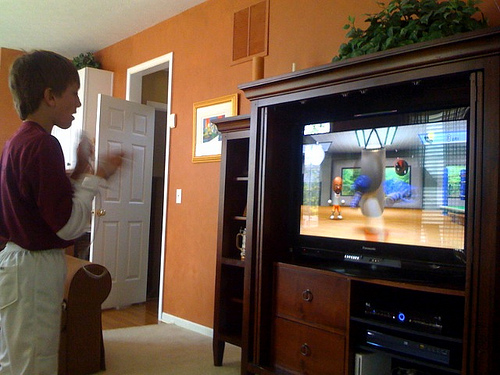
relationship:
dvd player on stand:
[356, 295, 459, 336] [240, 26, 498, 374]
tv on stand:
[282, 102, 469, 284] [240, 26, 498, 374]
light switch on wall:
[176, 188, 182, 203] [0, 1, 498, 325]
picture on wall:
[191, 92, 239, 163] [0, 1, 498, 325]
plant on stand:
[326, 1, 492, 64] [240, 26, 498, 374]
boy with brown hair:
[1, 50, 125, 374] [6, 48, 80, 121]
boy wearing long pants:
[1, 50, 125, 374] [0, 241, 65, 372]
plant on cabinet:
[73, 53, 102, 72] [52, 65, 112, 235]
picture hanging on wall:
[191, 92, 239, 163] [0, 1, 498, 325]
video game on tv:
[299, 118, 469, 249] [282, 102, 469, 284]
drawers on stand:
[267, 263, 351, 374] [240, 26, 498, 374]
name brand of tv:
[360, 245, 375, 252] [282, 102, 469, 284]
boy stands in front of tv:
[1, 50, 125, 374] [282, 102, 469, 284]